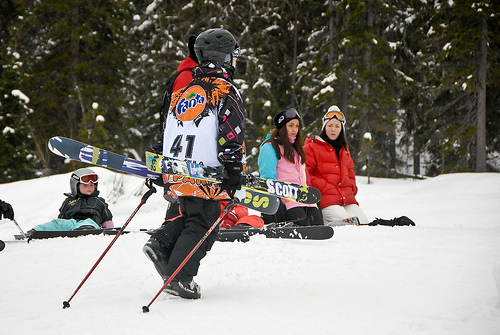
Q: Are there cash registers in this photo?
A: No, there are no cash registers.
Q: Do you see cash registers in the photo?
A: No, there are no cash registers.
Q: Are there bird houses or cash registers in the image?
A: No, there are no cash registers or bird houses.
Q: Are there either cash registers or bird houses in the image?
A: No, there are no cash registers or bird houses.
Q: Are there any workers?
A: No, there are no workers.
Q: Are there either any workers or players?
A: No, there are no workers or players.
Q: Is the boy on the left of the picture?
A: Yes, the boy is on the left of the image.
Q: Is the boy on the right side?
A: No, the boy is on the left of the image.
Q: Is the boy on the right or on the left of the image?
A: The boy is on the left of the image.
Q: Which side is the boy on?
A: The boy is on the left of the image.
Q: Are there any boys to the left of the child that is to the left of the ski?
A: Yes, there is a boy to the left of the child.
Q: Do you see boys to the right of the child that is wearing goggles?
A: No, the boy is to the left of the child.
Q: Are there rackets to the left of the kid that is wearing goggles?
A: No, there is a boy to the left of the child.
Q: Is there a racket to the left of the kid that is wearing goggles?
A: No, there is a boy to the left of the child.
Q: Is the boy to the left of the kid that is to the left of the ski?
A: Yes, the boy is to the left of the kid.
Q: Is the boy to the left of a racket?
A: No, the boy is to the left of the kid.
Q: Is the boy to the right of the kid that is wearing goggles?
A: No, the boy is to the left of the kid.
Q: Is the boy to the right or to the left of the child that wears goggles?
A: The boy is to the left of the child.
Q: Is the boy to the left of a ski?
A: Yes, the boy is to the left of a ski.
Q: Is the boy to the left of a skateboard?
A: No, the boy is to the left of a ski.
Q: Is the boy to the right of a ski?
A: No, the boy is to the left of a ski.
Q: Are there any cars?
A: No, there are no cars.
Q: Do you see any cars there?
A: No, there are no cars.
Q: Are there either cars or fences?
A: No, there are no cars or fences.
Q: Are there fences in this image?
A: No, there are no fences.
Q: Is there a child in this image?
A: Yes, there is a child.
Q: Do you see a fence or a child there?
A: Yes, there is a child.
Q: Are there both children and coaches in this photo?
A: No, there is a child but no coaches.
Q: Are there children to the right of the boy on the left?
A: Yes, there is a child to the right of the boy.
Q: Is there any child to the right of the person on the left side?
A: Yes, there is a child to the right of the boy.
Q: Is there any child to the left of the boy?
A: No, the child is to the right of the boy.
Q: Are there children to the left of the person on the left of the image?
A: No, the child is to the right of the boy.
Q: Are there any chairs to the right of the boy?
A: No, there is a child to the right of the boy.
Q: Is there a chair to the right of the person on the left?
A: No, there is a child to the right of the boy.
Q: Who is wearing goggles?
A: The kid is wearing goggles.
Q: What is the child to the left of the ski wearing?
A: The kid is wearing goggles.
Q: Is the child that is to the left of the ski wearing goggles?
A: Yes, the child is wearing goggles.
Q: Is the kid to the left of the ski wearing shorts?
A: No, the kid is wearing goggles.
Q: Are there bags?
A: No, there are no bags.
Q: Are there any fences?
A: No, there are no fences.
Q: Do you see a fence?
A: No, there are no fences.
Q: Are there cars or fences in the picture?
A: No, there are no fences or cars.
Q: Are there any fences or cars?
A: No, there are no fences or cars.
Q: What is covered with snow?
A: The trees are covered with snow.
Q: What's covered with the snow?
A: The trees are covered with snow.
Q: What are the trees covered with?
A: The trees are covered with snow.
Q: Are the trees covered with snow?
A: Yes, the trees are covered with snow.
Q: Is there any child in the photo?
A: Yes, there is a child.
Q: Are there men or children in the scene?
A: Yes, there is a child.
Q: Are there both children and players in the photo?
A: No, there is a child but no players.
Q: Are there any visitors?
A: No, there are no visitors.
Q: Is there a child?
A: Yes, there is a child.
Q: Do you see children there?
A: Yes, there is a child.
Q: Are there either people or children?
A: Yes, there is a child.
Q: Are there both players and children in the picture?
A: No, there is a child but no players.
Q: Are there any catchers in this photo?
A: No, there are no catchers.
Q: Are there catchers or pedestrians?
A: No, there are no catchers or pedestrians.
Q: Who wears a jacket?
A: The child wears a jacket.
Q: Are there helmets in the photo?
A: Yes, there is a helmet.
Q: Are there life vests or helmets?
A: Yes, there is a helmet.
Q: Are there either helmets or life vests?
A: Yes, there is a helmet.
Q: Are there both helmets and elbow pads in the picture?
A: No, there is a helmet but no elbow pads.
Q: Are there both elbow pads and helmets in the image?
A: No, there is a helmet but no elbow pads.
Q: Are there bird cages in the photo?
A: No, there are no bird cages.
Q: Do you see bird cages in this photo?
A: No, there are no bird cages.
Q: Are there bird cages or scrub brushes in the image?
A: No, there are no bird cages or scrub brushes.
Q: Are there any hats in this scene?
A: Yes, there is a hat.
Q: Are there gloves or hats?
A: Yes, there is a hat.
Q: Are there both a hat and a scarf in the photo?
A: No, there is a hat but no scarves.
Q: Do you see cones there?
A: No, there are no cones.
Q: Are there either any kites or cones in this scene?
A: No, there are no cones or kites.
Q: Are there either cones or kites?
A: No, there are no cones or kites.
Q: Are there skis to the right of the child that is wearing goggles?
A: Yes, there is a ski to the right of the kid.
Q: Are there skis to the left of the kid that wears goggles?
A: No, the ski is to the right of the kid.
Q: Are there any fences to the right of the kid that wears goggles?
A: No, there is a ski to the right of the child.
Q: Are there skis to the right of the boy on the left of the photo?
A: Yes, there is a ski to the right of the boy.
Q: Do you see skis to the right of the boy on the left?
A: Yes, there is a ski to the right of the boy.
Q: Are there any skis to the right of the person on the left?
A: Yes, there is a ski to the right of the boy.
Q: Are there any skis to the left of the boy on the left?
A: No, the ski is to the right of the boy.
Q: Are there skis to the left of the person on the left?
A: No, the ski is to the right of the boy.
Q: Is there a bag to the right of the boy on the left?
A: No, there is a ski to the right of the boy.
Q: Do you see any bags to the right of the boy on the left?
A: No, there is a ski to the right of the boy.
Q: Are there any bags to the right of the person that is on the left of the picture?
A: No, there is a ski to the right of the boy.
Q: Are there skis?
A: Yes, there are skis.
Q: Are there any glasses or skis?
A: Yes, there are skis.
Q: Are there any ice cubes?
A: No, there are no ice cubes.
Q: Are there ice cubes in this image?
A: No, there are no ice cubes.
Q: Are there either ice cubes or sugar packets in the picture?
A: No, there are no ice cubes or sugar packets.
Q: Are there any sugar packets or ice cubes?
A: No, there are no ice cubes or sugar packets.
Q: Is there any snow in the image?
A: Yes, there is snow.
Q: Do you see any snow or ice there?
A: Yes, there is snow.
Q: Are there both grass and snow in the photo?
A: No, there is snow but no grass.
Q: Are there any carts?
A: No, there are no carts.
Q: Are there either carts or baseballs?
A: No, there are no carts or baseballs.